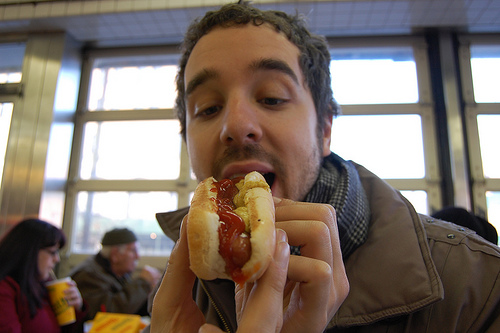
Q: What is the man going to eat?
A: A burger.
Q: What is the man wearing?
A: A brown stylish jacket.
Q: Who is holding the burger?
A: The man with brown hair.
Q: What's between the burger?
A: Hot dog.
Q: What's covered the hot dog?
A: Ketchup and mustard.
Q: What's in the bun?
A: A hot dog.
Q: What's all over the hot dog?
A: Condiments.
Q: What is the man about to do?
A: Ready to bite the hotdog.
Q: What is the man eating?
A: A hot dog.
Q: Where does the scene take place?
A: In a restaurant.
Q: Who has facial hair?
A: Man eating hot dog.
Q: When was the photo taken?
A: During the daytime.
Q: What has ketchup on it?
A: Hot dog.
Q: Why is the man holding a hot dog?
A: To eat it.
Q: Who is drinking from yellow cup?
A: The woman.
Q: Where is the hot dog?
A: In hot dog bun.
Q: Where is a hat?
A: On old man's head.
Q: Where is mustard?
A: On hot dog.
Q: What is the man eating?
A: Bun.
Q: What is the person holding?
A: Food.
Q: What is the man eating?
A: Food.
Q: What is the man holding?
A: Food.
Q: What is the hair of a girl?
A: Black.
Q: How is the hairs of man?
A: Short.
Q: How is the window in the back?
A: Large.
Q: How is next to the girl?
A: Old person.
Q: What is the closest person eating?
A: Hot dog.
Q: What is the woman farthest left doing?
A: Drinking.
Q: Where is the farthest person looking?
A: Right.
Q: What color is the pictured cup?
A: Yellow.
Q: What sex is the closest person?
A: Male.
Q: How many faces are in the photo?
A: 3.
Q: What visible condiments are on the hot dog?
A: Mustard and ketchup.